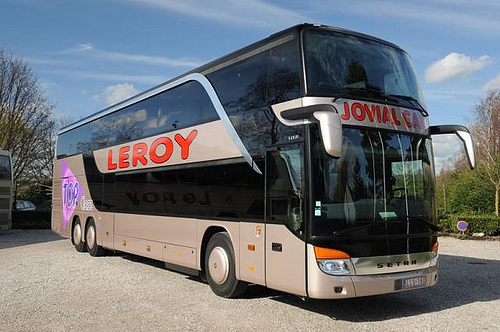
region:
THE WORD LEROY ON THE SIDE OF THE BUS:
[105, 127, 200, 170]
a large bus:
[23, 8, 472, 299]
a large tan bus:
[49, 20, 464, 308]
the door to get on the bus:
[265, 140, 306, 304]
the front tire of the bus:
[205, 227, 247, 302]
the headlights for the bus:
[312, 243, 447, 274]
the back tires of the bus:
[65, 213, 100, 253]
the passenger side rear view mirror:
[305, 105, 343, 157]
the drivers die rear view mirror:
[430, 123, 477, 175]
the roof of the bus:
[45, 20, 440, 133]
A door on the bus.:
[263, 147, 305, 292]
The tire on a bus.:
[199, 229, 238, 296]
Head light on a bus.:
[312, 243, 354, 274]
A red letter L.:
[101, 145, 116, 170]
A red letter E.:
[116, 143, 131, 168]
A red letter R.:
[131, 142, 148, 166]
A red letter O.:
[148, 136, 174, 163]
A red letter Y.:
[173, 128, 199, 159]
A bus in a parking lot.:
[49, 19, 478, 300]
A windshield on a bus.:
[313, 123, 438, 258]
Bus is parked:
[40, 20, 480, 305]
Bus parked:
[42, 17, 480, 307]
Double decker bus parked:
[40, 15, 477, 307]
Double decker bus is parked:
[42, 17, 480, 316]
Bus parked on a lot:
[41, 19, 477, 312]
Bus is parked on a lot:
[44, 18, 481, 306]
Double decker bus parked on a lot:
[47, 20, 480, 303]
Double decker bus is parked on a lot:
[42, 17, 484, 317]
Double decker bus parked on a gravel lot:
[38, 22, 483, 304]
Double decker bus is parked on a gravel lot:
[35, 13, 483, 303]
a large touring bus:
[12, 20, 495, 312]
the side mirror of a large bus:
[313, 103, 351, 164]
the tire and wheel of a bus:
[183, 221, 255, 297]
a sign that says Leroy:
[92, 138, 248, 170]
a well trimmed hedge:
[458, 218, 498, 234]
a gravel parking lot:
[30, 257, 125, 328]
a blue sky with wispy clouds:
[50, 6, 140, 84]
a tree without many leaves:
[5, 46, 51, 156]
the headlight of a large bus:
[312, 244, 359, 289]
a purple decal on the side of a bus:
[52, 160, 89, 230]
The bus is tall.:
[34, 13, 481, 312]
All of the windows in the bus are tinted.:
[37, 12, 492, 317]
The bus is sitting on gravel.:
[3, 16, 499, 330]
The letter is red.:
[101, 143, 118, 173]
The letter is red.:
[116, 141, 131, 171]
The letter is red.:
[130, 136, 150, 170]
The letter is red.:
[145, 132, 171, 167]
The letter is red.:
[172, 125, 195, 161]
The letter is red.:
[338, 98, 349, 120]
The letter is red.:
[349, 98, 367, 125]